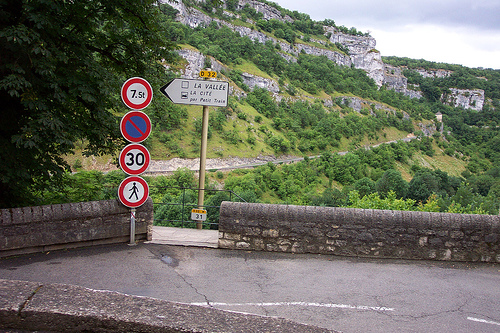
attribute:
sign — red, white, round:
[103, 54, 159, 212]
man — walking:
[125, 182, 145, 209]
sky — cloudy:
[354, 4, 491, 64]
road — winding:
[208, 134, 341, 168]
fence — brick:
[222, 203, 361, 264]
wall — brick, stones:
[230, 188, 413, 255]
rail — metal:
[159, 182, 220, 226]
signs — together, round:
[120, 74, 153, 215]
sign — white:
[154, 71, 246, 129]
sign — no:
[123, 114, 154, 140]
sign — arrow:
[165, 78, 233, 116]